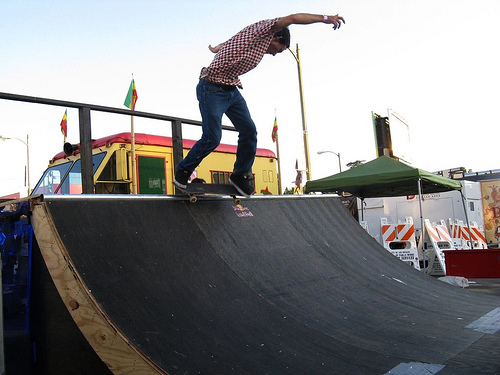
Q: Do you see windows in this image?
A: Yes, there is a window.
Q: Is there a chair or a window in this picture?
A: Yes, there is a window.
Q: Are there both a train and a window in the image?
A: No, there is a window but no trains.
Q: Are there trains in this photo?
A: No, there are no trains.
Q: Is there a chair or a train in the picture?
A: No, there are no trains or chairs.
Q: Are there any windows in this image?
A: Yes, there are windows.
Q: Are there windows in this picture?
A: Yes, there are windows.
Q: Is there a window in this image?
A: Yes, there are windows.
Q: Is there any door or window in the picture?
A: Yes, there are windows.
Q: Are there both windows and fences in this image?
A: Yes, there are both windows and a fence.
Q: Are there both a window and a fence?
A: Yes, there are both a window and a fence.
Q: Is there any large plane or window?
A: Yes, there are large windows.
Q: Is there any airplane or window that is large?
A: Yes, the windows are large.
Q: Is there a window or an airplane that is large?
A: Yes, the windows are large.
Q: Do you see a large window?
A: Yes, there are large windows.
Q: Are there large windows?
A: Yes, there are large windows.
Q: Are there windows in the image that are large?
A: Yes, there are windows that are large.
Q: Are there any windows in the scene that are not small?
A: Yes, there are large windows.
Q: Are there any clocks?
A: No, there are no clocks.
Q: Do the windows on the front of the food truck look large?
A: Yes, the windows are large.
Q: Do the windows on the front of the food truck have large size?
A: Yes, the windows are large.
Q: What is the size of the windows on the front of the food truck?
A: The windows are large.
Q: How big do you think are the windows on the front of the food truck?
A: The windows are large.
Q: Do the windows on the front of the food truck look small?
A: No, the windows are large.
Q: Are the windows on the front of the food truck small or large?
A: The windows are large.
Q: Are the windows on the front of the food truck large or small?
A: The windows are large.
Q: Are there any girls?
A: No, there are no girls.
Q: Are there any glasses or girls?
A: No, there are no girls or glasses.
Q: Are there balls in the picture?
A: No, there are no balls.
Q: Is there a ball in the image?
A: No, there are no balls.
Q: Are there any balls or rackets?
A: No, there are no balls or rackets.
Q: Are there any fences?
A: Yes, there is a fence.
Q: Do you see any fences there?
A: Yes, there is a fence.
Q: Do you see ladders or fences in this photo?
A: Yes, there is a fence.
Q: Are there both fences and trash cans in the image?
A: No, there is a fence but no trash cans.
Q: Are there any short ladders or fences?
A: Yes, there is a short fence.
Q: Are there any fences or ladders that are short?
A: Yes, the fence is short.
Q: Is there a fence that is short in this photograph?
A: Yes, there is a short fence.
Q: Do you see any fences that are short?
A: Yes, there is a fence that is short.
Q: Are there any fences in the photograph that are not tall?
A: Yes, there is a short fence.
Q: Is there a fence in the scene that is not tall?
A: Yes, there is a short fence.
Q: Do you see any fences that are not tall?
A: Yes, there is a short fence.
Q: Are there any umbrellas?
A: No, there are no umbrellas.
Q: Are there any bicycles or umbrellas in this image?
A: No, there are no umbrellas or bicycles.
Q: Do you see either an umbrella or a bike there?
A: No, there are no umbrellas or bikes.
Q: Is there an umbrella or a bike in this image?
A: No, there are no umbrellas or bikes.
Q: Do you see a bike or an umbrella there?
A: No, there are no umbrellas or bikes.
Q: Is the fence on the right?
A: Yes, the fence is on the right of the image.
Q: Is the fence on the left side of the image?
A: No, the fence is on the right of the image.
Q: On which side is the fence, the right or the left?
A: The fence is on the right of the image.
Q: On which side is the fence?
A: The fence is on the right of the image.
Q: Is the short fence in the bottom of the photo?
A: Yes, the fence is in the bottom of the image.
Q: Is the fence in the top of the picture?
A: No, the fence is in the bottom of the image.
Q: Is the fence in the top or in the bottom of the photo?
A: The fence is in the bottom of the image.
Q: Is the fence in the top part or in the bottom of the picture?
A: The fence is in the bottom of the image.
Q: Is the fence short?
A: Yes, the fence is short.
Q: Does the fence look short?
A: Yes, the fence is short.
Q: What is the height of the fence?
A: The fence is short.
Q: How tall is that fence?
A: The fence is short.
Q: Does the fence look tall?
A: No, the fence is short.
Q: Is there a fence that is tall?
A: No, there is a fence but it is short.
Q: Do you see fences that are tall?
A: No, there is a fence but it is short.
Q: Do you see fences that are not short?
A: No, there is a fence but it is short.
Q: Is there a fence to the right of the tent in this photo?
A: Yes, there is a fence to the right of the tent.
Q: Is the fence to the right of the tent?
A: Yes, the fence is to the right of the tent.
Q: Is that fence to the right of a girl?
A: No, the fence is to the right of the tent.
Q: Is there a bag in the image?
A: No, there are no bags.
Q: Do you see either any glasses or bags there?
A: No, there are no bags or glasses.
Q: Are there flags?
A: Yes, there is a flag.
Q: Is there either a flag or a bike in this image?
A: Yes, there is a flag.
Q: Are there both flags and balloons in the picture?
A: No, there is a flag but no balloons.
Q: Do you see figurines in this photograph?
A: No, there are no figurines.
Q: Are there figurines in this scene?
A: No, there are no figurines.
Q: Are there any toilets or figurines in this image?
A: No, there are no figurines or toilets.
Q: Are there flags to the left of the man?
A: Yes, there is a flag to the left of the man.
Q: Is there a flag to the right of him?
A: No, the flag is to the left of the man.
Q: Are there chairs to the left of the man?
A: No, there is a flag to the left of the man.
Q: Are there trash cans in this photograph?
A: No, there are no trash cans.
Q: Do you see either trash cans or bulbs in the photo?
A: No, there are no trash cans or bulbs.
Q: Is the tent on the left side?
A: No, the tent is on the right of the image.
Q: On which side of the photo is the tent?
A: The tent is on the right of the image.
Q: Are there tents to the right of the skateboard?
A: Yes, there is a tent to the right of the skateboard.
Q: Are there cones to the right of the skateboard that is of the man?
A: No, there is a tent to the right of the skateboard.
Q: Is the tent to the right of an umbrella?
A: No, the tent is to the right of a skateboard.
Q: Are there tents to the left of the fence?
A: Yes, there is a tent to the left of the fence.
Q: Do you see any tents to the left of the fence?
A: Yes, there is a tent to the left of the fence.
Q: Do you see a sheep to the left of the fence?
A: No, there is a tent to the left of the fence.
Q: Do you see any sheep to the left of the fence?
A: No, there is a tent to the left of the fence.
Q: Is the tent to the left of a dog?
A: No, the tent is to the left of the fence.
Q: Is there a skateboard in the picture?
A: Yes, there is a skateboard.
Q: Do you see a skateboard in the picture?
A: Yes, there is a skateboard.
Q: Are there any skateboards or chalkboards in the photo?
A: Yes, there is a skateboard.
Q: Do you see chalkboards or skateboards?
A: Yes, there is a skateboard.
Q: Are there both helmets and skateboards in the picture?
A: No, there is a skateboard but no helmets.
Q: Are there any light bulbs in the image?
A: No, there are no light bulbs.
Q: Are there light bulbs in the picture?
A: No, there are no light bulbs.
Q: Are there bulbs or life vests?
A: No, there are no bulbs or life vests.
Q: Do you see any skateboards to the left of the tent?
A: Yes, there is a skateboard to the left of the tent.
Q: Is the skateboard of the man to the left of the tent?
A: Yes, the skateboard is to the left of the tent.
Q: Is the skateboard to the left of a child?
A: No, the skateboard is to the left of the tent.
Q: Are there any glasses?
A: No, there are no glasses.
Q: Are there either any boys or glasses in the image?
A: No, there are no glasses or boys.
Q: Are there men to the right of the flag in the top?
A: Yes, there is a man to the right of the flag.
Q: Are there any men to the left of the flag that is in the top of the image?
A: No, the man is to the right of the flag.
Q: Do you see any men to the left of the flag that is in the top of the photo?
A: No, the man is to the right of the flag.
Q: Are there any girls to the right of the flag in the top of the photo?
A: No, there is a man to the right of the flag.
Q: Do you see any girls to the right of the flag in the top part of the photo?
A: No, there is a man to the right of the flag.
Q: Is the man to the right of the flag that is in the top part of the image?
A: Yes, the man is to the right of the flag.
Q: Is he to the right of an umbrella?
A: No, the man is to the right of the flag.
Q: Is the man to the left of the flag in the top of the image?
A: No, the man is to the right of the flag.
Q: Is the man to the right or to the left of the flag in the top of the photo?
A: The man is to the right of the flag.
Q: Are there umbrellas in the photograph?
A: No, there are no umbrellas.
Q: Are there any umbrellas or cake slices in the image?
A: No, there are no umbrellas or cake slices.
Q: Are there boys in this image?
A: No, there are no boys.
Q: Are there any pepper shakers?
A: No, there are no pepper shakers.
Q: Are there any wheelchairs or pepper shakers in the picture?
A: No, there are no pepper shakers or wheelchairs.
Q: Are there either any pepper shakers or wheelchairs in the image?
A: No, there are no pepper shakers or wheelchairs.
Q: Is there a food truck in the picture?
A: Yes, there is a food truck.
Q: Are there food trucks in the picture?
A: Yes, there is a food truck.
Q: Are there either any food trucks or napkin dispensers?
A: Yes, there is a food truck.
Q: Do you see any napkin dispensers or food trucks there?
A: Yes, there is a food truck.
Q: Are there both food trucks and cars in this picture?
A: No, there is a food truck but no cars.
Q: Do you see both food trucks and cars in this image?
A: No, there is a food truck but no cars.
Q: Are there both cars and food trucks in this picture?
A: No, there is a food truck but no cars.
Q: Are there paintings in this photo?
A: No, there are no paintings.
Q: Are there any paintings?
A: No, there are no paintings.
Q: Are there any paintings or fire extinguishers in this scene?
A: No, there are no paintings or fire extinguishers.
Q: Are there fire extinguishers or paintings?
A: No, there are no paintings or fire extinguishers.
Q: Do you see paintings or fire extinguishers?
A: No, there are no paintings or fire extinguishers.